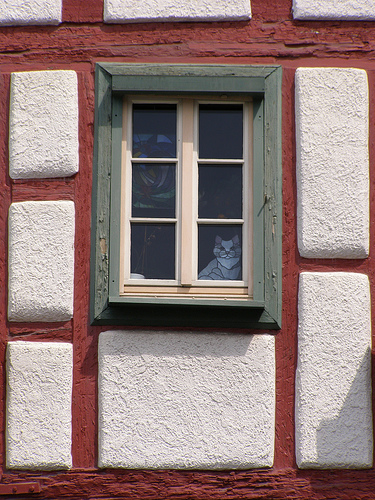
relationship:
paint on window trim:
[96, 233, 109, 258] [104, 273, 264, 307]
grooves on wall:
[0, 473, 375, 498] [0, 0, 374, 498]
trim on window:
[0, 0, 374, 498] [122, 97, 248, 286]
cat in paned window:
[200, 234, 240, 276] [109, 87, 266, 308]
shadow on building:
[94, 82, 271, 142] [2, 0, 371, 496]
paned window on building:
[109, 87, 266, 308] [2, 0, 371, 496]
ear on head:
[213, 233, 223, 244] [212, 236, 239, 260]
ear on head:
[228, 231, 241, 245] [212, 236, 239, 260]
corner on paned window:
[115, 264, 141, 295] [109, 87, 266, 308]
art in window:
[132, 128, 184, 213] [130, 96, 258, 297]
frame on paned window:
[92, 52, 288, 97] [109, 87, 266, 308]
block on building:
[296, 273, 373, 469] [2, 0, 371, 496]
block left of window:
[290, 51, 373, 286] [67, 40, 310, 340]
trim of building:
[4, 2, 373, 497] [2, 0, 371, 496]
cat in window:
[199, 235, 243, 280] [194, 217, 250, 282]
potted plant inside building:
[118, 223, 190, 298] [2, 0, 371, 496]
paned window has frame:
[109, 87, 266, 308] [87, 61, 280, 327]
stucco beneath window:
[111, 329, 265, 457] [122, 97, 248, 286]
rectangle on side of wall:
[5, 338, 73, 470] [21, 52, 372, 487]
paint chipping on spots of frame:
[262, 190, 279, 269] [97, 88, 267, 308]